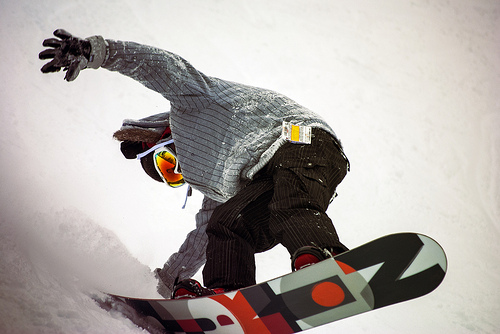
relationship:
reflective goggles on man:
[149, 145, 185, 191] [35, 28, 349, 298]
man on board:
[35, 28, 349, 298] [88, 230, 449, 334]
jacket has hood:
[87, 34, 340, 299] [113, 111, 170, 145]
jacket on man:
[87, 34, 340, 299] [35, 28, 349, 298]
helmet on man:
[138, 145, 185, 189] [35, 28, 349, 298]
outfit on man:
[85, 33, 348, 294] [35, 28, 349, 298]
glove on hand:
[37, 28, 90, 83] [37, 27, 89, 81]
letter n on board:
[332, 232, 446, 309] [88, 230, 449, 334]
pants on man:
[201, 126, 349, 290] [35, 28, 349, 298]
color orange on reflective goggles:
[154, 149, 179, 184] [149, 145, 185, 191]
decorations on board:
[151, 226, 448, 331] [88, 230, 449, 334]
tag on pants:
[281, 121, 313, 145] [201, 126, 349, 290]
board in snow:
[88, 230, 449, 334] [56, 214, 166, 332]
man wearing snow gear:
[35, 28, 349, 298] [37, 26, 350, 299]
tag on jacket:
[281, 121, 313, 145] [87, 34, 340, 299]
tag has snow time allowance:
[281, 121, 313, 145] [280, 121, 313, 144]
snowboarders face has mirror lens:
[136, 143, 186, 188] [152, 150, 184, 189]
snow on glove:
[64, 53, 89, 69] [37, 28, 90, 83]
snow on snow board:
[49, 243, 96, 303] [75, 276, 145, 330]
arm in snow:
[136, 259, 193, 299] [55, 208, 159, 294]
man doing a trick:
[35, 28, 349, 298] [37, 28, 449, 332]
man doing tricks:
[35, 28, 349, 298] [35, 27, 448, 332]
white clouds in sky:
[407, 72, 454, 128] [351, 2, 485, 186]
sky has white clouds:
[410, 54, 458, 104] [411, 61, 431, 81]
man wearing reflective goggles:
[35, 28, 349, 298] [149, 145, 185, 191]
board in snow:
[88, 230, 449, 334] [1, 0, 499, 331]